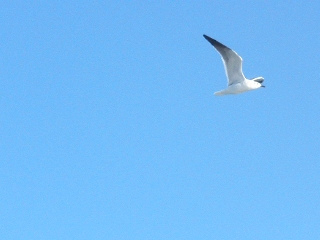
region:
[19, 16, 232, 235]
the sky is blue and clear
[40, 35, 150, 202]
the sky is blue and clear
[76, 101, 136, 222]
the sky is blue and clear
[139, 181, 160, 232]
the sky is blue and clear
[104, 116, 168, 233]
the sky is blue and clear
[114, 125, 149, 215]
the sky is blue and clear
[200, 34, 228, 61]
tip of wing is black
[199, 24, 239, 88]
bird has white wing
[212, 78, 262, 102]
bird has white body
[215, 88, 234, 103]
bird has white tail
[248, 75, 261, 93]
bird has white head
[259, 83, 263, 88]
bird has black beak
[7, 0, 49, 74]
sky is blue and cloudless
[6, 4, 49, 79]
sky is blue and clear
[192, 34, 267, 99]
bird is flying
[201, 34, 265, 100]
bird is in the sky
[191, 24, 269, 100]
Bird in the sky.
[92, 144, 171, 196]
The sky is black.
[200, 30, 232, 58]
Tip of the wing is black.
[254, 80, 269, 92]
The beak is black.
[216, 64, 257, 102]
Most of the body is white.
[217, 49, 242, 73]
Part of the wing is grey.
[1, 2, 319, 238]
Picture of a bird flying.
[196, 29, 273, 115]
The wings are spread.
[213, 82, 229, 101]
The tail is white.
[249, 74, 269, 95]
The eye is small.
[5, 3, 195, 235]
bright sunny sky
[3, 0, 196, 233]
cloudless light blue sky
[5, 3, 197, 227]
light blue daylight sky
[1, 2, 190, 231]
sunny day light sky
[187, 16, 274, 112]
flying sea gull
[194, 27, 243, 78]
gray tipped white gull wing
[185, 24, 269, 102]
gray and white sea bird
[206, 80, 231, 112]
light gray gull's tail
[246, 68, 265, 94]
white gull's head with dark beak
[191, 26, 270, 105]
sea gull on the wing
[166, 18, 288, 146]
blue sky behind bird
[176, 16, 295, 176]
bird flying through sky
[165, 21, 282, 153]
bird flying among blue sky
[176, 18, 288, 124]
a mostly white bird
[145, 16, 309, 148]
a white bird with black tips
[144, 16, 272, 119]
a seagull in the air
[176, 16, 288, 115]
bird with wings extended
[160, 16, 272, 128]
bird in flight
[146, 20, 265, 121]
seagull flying through sky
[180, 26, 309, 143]
a singular seagull flying